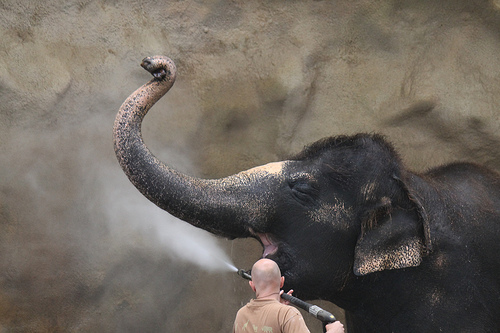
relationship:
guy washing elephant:
[232, 257, 342, 331] [112, 55, 500, 333]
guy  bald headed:
[232, 257, 343, 333] [245, 256, 286, 292]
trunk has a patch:
[114, 56, 240, 230] [204, 158, 302, 186]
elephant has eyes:
[107, 52, 479, 315] [288, 172, 326, 205]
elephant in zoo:
[112, 55, 500, 333] [9, 5, 477, 319]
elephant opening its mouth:
[112, 55, 500, 333] [230, 220, 274, 267]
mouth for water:
[230, 220, 274, 267] [96, 135, 236, 274]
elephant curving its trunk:
[112, 55, 500, 333] [114, 56, 240, 230]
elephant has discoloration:
[112, 55, 500, 333] [356, 236, 426, 276]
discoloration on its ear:
[356, 236, 426, 276] [348, 175, 435, 276]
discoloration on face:
[309, 194, 359, 235] [242, 153, 353, 296]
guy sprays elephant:
[232, 257, 343, 333] [112, 55, 500, 333]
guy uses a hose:
[232, 257, 343, 333] [231, 255, 337, 317]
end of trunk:
[107, 51, 183, 171] [114, 56, 240, 230]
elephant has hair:
[107, 52, 479, 315] [299, 130, 400, 158]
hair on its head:
[299, 130, 400, 158] [111, 51, 419, 285]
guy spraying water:
[232, 257, 343, 333] [56, 120, 248, 274]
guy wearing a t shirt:
[232, 257, 343, 333] [233, 299, 299, 325]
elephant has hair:
[107, 52, 479, 315] [292, 131, 403, 164]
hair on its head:
[292, 131, 403, 164] [111, 51, 419, 285]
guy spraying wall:
[232, 257, 343, 333] [0, 0, 497, 330]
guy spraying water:
[232, 257, 343, 333] [84, 129, 241, 275]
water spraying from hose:
[85, 113, 244, 277] [239, 271, 337, 333]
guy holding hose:
[232, 257, 343, 333] [239, 271, 337, 333]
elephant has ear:
[112, 55, 500, 333] [352, 170, 436, 280]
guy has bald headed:
[232, 257, 343, 333] [251, 258, 281, 293]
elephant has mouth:
[112, 55, 500, 333] [245, 224, 281, 275]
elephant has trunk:
[112, 55, 500, 333] [114, 56, 240, 230]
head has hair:
[108, 53, 415, 307] [294, 127, 406, 181]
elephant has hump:
[112, 55, 500, 333] [425, 156, 499, 181]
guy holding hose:
[232, 257, 343, 333] [235, 268, 335, 320]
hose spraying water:
[235, 272, 335, 322] [84, 129, 241, 275]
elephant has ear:
[112, 55, 500, 333] [345, 168, 435, 279]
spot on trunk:
[243, 159, 297, 179] [114, 56, 240, 230]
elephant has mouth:
[112, 55, 500, 333] [244, 226, 276, 271]